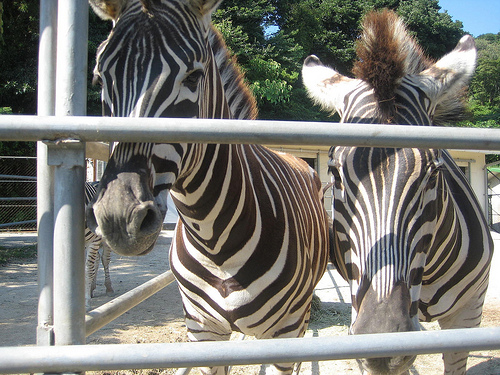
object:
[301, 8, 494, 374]
zebra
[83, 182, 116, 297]
zebra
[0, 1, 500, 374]
fence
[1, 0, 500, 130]
trees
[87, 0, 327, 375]
zebra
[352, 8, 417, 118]
mane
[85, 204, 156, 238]
nostrills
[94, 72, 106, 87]
eye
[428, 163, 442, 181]
eye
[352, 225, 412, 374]
muzzle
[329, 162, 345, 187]
eye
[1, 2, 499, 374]
poles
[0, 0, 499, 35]
sky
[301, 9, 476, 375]
head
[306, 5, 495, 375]
fur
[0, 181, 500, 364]
ground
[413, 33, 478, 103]
ears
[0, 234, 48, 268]
grass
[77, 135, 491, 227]
building